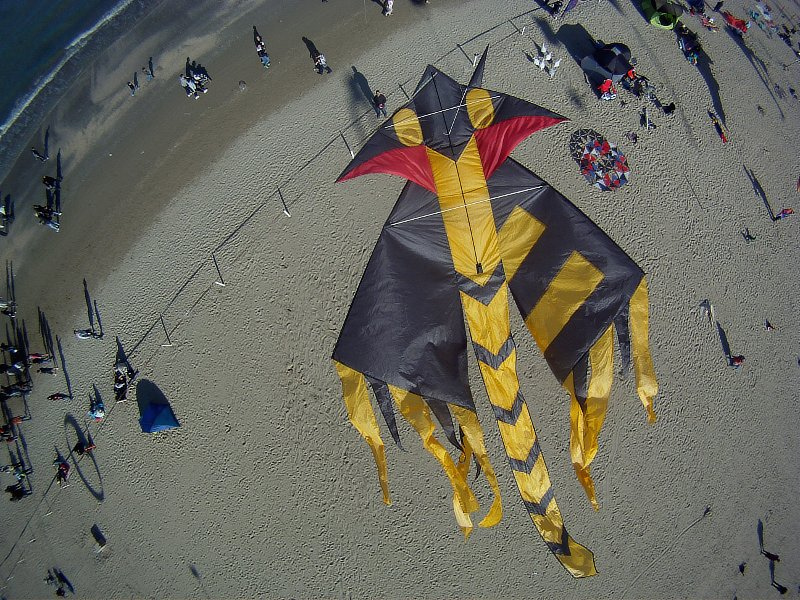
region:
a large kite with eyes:
[305, 46, 703, 593]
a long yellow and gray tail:
[463, 270, 607, 598]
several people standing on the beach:
[4, 72, 793, 596]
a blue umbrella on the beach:
[128, 395, 186, 447]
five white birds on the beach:
[526, 38, 567, 83]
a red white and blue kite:
[565, 123, 654, 203]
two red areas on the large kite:
[344, 115, 568, 205]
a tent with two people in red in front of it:
[576, 43, 640, 94]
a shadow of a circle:
[40, 407, 125, 507]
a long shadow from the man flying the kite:
[343, 58, 393, 124]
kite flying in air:
[320, 36, 685, 597]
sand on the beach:
[208, 468, 354, 598]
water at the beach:
[0, 0, 96, 110]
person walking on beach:
[303, 51, 338, 77]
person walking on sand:
[724, 345, 754, 378]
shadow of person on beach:
[735, 163, 778, 221]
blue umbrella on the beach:
[119, 405, 193, 447]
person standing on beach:
[40, 451, 83, 497]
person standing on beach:
[88, 392, 117, 425]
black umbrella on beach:
[594, 36, 642, 85]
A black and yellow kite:
[334, 59, 655, 583]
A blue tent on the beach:
[117, 392, 189, 441]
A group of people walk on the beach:
[174, 65, 215, 100]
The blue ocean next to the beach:
[3, 6, 148, 147]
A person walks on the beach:
[730, 346, 750, 380]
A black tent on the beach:
[581, 28, 641, 114]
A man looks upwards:
[363, 89, 392, 119]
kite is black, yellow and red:
[313, 45, 694, 594]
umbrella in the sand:
[136, 405, 180, 442]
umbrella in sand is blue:
[130, 395, 183, 438]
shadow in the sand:
[61, 408, 107, 509]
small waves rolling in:
[0, 0, 130, 130]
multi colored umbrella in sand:
[563, 120, 614, 176]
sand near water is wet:
[0, 0, 458, 405]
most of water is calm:
[0, 1, 118, 121]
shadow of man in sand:
[339, 59, 381, 112]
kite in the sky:
[326, 32, 674, 576]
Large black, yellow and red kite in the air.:
[328, 46, 660, 582]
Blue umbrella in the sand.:
[136, 400, 180, 435]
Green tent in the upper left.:
[634, 2, 694, 34]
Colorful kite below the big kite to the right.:
[570, 127, 635, 191]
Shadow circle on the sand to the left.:
[60, 410, 126, 506]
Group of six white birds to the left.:
[525, 39, 567, 80]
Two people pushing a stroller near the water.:
[174, 56, 225, 102]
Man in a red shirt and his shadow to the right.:
[712, 318, 749, 372]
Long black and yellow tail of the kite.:
[456, 264, 605, 598]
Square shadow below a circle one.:
[86, 523, 123, 545]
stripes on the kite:
[464, 260, 572, 552]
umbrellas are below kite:
[572, 122, 650, 202]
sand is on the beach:
[189, 353, 379, 555]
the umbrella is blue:
[126, 371, 184, 437]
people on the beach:
[16, 330, 131, 471]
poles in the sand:
[172, 178, 318, 322]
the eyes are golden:
[395, 96, 510, 142]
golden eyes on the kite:
[390, 100, 498, 142]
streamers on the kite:
[336, 369, 517, 541]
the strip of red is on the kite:
[350, 147, 516, 185]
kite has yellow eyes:
[369, 77, 439, 173]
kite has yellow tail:
[444, 164, 610, 583]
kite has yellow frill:
[557, 365, 694, 504]